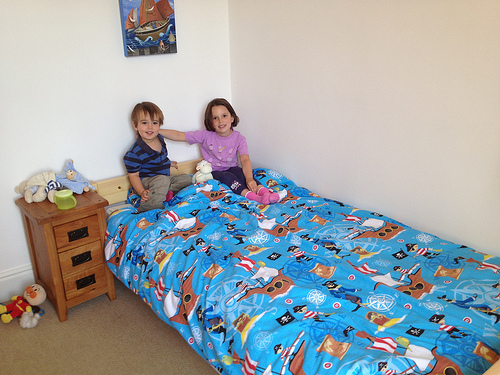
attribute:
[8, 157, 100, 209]
animals — stuffed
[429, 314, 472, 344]
pirates — design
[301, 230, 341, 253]
pirates — design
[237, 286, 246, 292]
pirates — design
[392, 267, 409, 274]
pirates — design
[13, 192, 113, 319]
wooden dresser — little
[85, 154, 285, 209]
bed head — wooden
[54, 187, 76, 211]
tea cup — green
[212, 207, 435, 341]
bedspread — blue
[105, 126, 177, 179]
shirt — blue, striped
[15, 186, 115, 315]
dresser — small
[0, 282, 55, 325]
animal — stuffed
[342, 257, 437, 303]
design — pirate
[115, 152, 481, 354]
bed — twin sized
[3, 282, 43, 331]
duck — stuffed